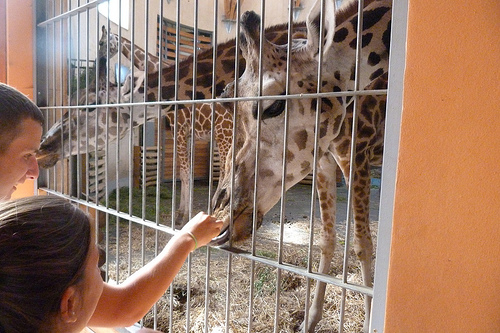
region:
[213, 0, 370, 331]
head of a giraffe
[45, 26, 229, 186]
two more giraffes in the enclosure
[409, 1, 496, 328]
orange-painted exterior wall of the enclosure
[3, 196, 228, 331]
female zoogoer petting the giraffe's head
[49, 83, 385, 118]
vertical bar of the enclosure gate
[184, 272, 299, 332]
grassy ground within the enclosure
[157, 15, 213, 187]
special gate for herding in giraffes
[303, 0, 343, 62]
giraffe's proper-left (viewer's right) ear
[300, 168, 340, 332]
giraffe's front right leg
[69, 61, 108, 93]
leaves and grass for giraffe consumption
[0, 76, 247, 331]
people at the zoo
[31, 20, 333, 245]
giraffes are being fed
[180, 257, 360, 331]
giraffes are standing in hay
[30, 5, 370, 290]
three giraffes behind bars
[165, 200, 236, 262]
a ladies hand at the bars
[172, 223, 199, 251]
the lady has a band around her wrist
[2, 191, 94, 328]
the girl has brown hair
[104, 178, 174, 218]
green grass in the corner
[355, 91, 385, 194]
the giraffes has spots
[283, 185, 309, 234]
concrete beyond the hay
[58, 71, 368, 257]
two giraffes being fed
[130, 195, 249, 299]
boy has hand near giraffe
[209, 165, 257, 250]
giraffe has brown nose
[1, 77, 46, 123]
boy has brown hair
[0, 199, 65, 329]
girl has brown hair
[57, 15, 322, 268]
cage has metal bars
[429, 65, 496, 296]
wall outside cage is orange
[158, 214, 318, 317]
ground inside cage has grass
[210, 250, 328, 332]
grass in cage is brown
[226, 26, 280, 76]
giraffes have brown horns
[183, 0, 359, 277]
a giraffe sniffing a hand.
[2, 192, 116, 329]
a child looking at a giraffe.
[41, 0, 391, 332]
bars on a giraffe cage door.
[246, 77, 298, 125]
a left giraffe eye.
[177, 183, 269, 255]
a mouth on a giraffe.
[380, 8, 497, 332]
a pink brick wall.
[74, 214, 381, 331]
a floor in a giraffe cage.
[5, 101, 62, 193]
a boy with short hair.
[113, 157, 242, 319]
a human arm.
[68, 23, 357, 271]
a giraffe inside of a cage.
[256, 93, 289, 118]
left eye of a giraffe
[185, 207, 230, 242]
person's right hand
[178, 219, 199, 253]
thin yellow bracelet on right wrist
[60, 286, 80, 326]
young female girl's ear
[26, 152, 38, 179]
young male's nose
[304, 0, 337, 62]
left ear of a giraffe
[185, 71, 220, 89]
dark spot on giraffe's neck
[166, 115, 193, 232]
long front leg of giraffe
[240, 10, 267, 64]
long antler of a giraffe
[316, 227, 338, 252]
leg joint of a giraffe